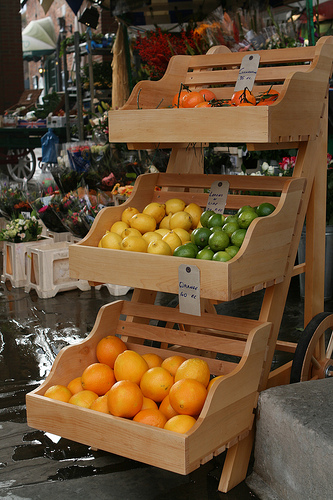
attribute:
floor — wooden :
[6, 460, 56, 477]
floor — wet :
[4, 352, 45, 368]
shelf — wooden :
[208, 392, 246, 436]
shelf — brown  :
[220, 392, 253, 427]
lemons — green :
[197, 225, 233, 254]